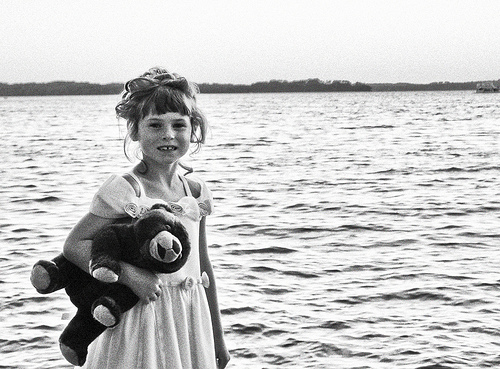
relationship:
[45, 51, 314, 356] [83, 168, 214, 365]
girl wearing dress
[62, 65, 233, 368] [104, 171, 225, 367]
girl wearing dress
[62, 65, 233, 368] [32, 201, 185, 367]
girl holds bear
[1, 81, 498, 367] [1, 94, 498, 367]
ripples on water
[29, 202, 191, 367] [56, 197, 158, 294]
bear in arm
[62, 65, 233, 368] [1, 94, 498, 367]
girl by water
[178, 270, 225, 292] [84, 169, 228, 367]
bows on dress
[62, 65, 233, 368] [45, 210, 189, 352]
girl and bear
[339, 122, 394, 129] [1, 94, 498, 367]
ripple in water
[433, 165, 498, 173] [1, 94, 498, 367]
ripple in water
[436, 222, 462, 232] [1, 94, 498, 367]
ripple in water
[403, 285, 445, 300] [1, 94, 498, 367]
ripple in water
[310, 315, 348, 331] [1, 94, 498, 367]
ripple in water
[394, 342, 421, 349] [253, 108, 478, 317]
ripple in water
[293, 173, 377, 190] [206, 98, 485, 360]
ripple in water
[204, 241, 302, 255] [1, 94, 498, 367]
ripple in water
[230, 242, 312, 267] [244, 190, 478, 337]
ripple in water